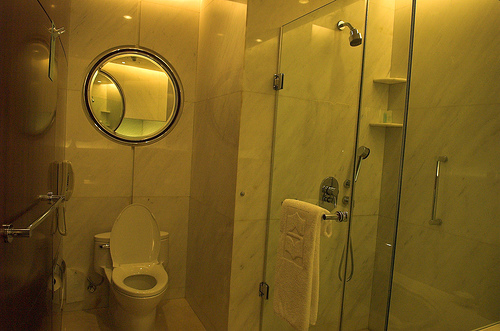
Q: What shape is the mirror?
A: Circle.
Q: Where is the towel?
A: Tower rack.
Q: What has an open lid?
A: The toilet.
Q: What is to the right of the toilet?
A: A shower.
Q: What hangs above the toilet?
A: A circular mirror.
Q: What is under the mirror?
A: A toilet.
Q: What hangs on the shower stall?
A: A towel.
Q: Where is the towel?
A: Hanging on the shower door.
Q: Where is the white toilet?
A: In a bathroom.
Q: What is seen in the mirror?
A: A reflection of the bathroom.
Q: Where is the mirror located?
A: On the wall behind the toilet.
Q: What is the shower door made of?
A: Glass.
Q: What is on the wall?
A: Faucet.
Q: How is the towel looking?
A: White.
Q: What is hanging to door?
A: Towel.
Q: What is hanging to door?
A: Towel.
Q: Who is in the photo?
A: Nobody.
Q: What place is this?
A: Bathroom.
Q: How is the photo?
A: Clear.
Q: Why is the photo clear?
A: The room is lit.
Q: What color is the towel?
A: White.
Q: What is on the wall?
A: Mirror.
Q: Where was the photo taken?
A: In the bathroom.